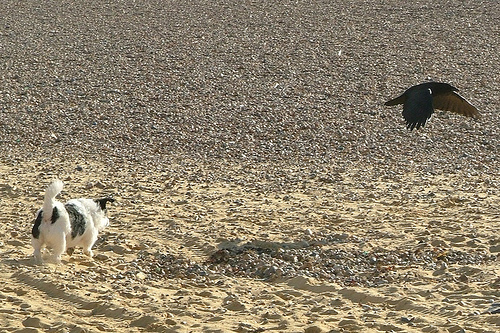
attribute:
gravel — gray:
[1, 2, 493, 182]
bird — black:
[384, 80, 481, 132]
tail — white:
[38, 180, 65, 210]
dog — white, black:
[27, 173, 124, 264]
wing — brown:
[432, 78, 487, 125]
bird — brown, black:
[379, 73, 486, 133]